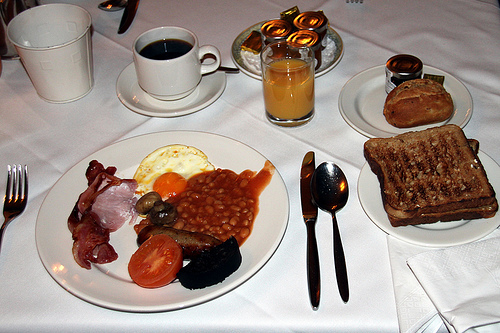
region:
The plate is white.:
[31, 123, 292, 318]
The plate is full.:
[28, 119, 294, 323]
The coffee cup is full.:
[105, 18, 238, 119]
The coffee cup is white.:
[108, 19, 236, 124]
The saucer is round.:
[109, 36, 231, 118]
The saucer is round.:
[333, 45, 484, 140]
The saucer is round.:
[349, 133, 499, 248]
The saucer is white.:
[353, 131, 498, 252]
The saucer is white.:
[331, 52, 481, 149]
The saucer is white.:
[113, 45, 232, 120]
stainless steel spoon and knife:
[296, 146, 352, 307]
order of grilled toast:
[348, 133, 495, 218]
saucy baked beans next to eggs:
[178, 165, 270, 234]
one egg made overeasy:
[133, 146, 211, 201]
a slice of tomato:
[131, 225, 185, 297]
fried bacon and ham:
[67, 153, 134, 257]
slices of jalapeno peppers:
[143, 194, 169, 226]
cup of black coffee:
[115, 24, 227, 111]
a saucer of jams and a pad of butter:
[238, 7, 342, 69]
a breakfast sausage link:
[134, 226, 221, 251]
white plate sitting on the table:
[34, 128, 291, 314]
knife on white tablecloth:
[300, 149, 321, 309]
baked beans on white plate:
[173, 159, 273, 247]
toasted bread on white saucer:
[357, 121, 498, 248]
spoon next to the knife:
[316, 159, 352, 309]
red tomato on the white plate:
[128, 234, 182, 289]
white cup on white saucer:
[116, 26, 226, 117]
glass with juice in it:
[258, 41, 313, 126]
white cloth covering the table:
[1, 2, 498, 331]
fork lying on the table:
[1, 164, 28, 245]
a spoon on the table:
[318, 164, 369, 299]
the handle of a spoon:
[330, 218, 355, 303]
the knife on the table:
[299, 152, 325, 314]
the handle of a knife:
[302, 226, 324, 313]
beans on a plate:
[195, 174, 250, 229]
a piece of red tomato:
[133, 237, 179, 280]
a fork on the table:
[1, 163, 26, 240]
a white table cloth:
[1, 99, 83, 165]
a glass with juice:
[263, 48, 315, 121]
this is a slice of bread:
[361, 124, 490, 229]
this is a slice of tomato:
[129, 235, 184, 280]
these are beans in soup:
[183, 154, 258, 244]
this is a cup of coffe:
[121, 26, 213, 94]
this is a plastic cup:
[9, 5, 101, 105]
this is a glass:
[260, 51, 332, 128]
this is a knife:
[284, 139, 340, 320]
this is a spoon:
[314, 155, 383, 310]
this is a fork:
[0, 165, 33, 247]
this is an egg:
[149, 169, 192, 206]